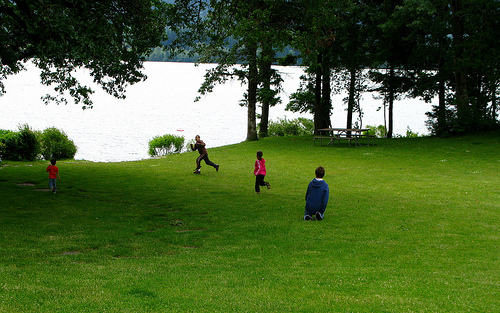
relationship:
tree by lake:
[213, 38, 291, 102] [98, 56, 325, 147]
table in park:
[312, 113, 373, 154] [45, 41, 421, 242]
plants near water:
[49, 132, 74, 144] [124, 87, 232, 125]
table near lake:
[318, 127, 372, 146] [98, 56, 325, 147]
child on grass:
[243, 149, 290, 188] [127, 209, 274, 302]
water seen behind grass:
[124, 87, 232, 125] [137, 136, 247, 254]